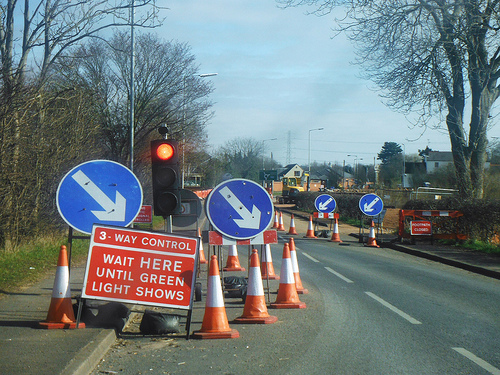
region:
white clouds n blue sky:
[198, 9, 239, 53]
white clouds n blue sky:
[277, 19, 342, 77]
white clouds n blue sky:
[210, 33, 275, 85]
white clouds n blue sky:
[267, 75, 334, 149]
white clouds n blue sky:
[232, 99, 293, 143]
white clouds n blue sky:
[243, 55, 329, 120]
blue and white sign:
[57, 155, 128, 232]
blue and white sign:
[206, 170, 266, 243]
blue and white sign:
[346, 180, 377, 217]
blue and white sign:
[292, 185, 339, 226]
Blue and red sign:
[207, 178, 274, 244]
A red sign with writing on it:
[76, 225, 193, 332]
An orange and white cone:
[193, 255, 237, 339]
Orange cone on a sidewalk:
[43, 244, 83, 326]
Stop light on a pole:
[149, 123, 180, 232]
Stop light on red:
[148, 138, 181, 215]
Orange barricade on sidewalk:
[397, 208, 471, 245]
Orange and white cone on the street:
[305, 215, 315, 237]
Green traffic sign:
[260, 168, 278, 180]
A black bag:
[139, 311, 183, 334]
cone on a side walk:
[35, 243, 88, 338]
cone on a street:
[191, 250, 236, 346]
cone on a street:
[240, 242, 286, 327]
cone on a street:
[270, 240, 301, 316]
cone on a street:
[361, 213, 389, 259]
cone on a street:
[326, 212, 341, 245]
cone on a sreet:
[301, 211, 321, 241]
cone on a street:
[285, 207, 302, 233]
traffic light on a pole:
[143, 122, 185, 222]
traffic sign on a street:
[348, 183, 387, 218]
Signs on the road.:
[66, 123, 348, 334]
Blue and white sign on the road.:
[165, 121, 372, 323]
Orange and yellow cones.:
[171, 220, 320, 370]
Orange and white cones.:
[136, 206, 429, 346]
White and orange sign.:
[45, 177, 253, 367]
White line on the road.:
[337, 258, 437, 372]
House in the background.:
[266, 99, 336, 194]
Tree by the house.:
[341, 108, 428, 235]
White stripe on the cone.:
[227, 250, 277, 316]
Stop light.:
[128, 119, 223, 224]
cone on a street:
[298, 206, 319, 246]